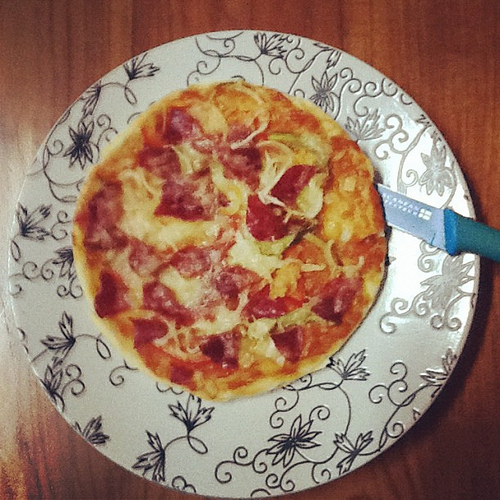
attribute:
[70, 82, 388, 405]
pizza — designed, small, individual size, meat cheese, sauc, thin crust, cooked, circle, round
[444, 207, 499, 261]
handle — blue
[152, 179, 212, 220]
pepperoni — red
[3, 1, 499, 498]
table — brown, wood, reflecting light, wood grain, carmel brown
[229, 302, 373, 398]
crust — golden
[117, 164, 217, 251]
cheese — melted, yellow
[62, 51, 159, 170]
plate — black, white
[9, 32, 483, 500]
plate — black, white, indoors, round, large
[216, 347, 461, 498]
design — black, floral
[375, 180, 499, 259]
knife — steel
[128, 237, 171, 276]
pepperoni — reed